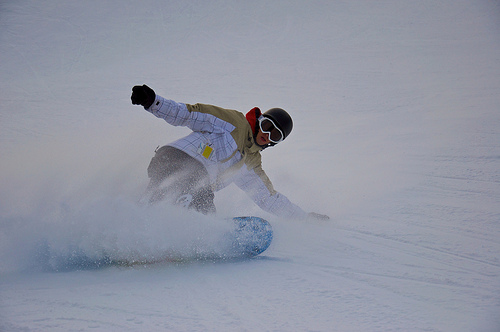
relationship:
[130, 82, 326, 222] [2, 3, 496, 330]
snowboarder coming down slope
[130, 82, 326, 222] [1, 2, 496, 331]
snowboarder stopping on snow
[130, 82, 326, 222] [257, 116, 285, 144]
snowboarder wearing goggles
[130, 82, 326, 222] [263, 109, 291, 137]
snowboarder wearing helmet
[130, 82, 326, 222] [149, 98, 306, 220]
snowboarder wearing jacket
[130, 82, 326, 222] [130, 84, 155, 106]
snowboarder wearing glove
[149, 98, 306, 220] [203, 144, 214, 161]
jacket has tag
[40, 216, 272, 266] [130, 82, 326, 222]
snowboard under snowboarder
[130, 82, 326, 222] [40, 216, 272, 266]
snowboarder on snowboard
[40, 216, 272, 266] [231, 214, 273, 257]
snowboard has tip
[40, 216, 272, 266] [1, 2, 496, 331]
snowboard behind snow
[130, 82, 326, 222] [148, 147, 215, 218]
snowboarder wearing pants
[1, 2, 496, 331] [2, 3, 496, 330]
snow on slope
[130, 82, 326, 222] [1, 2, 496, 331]
snowboarder on snow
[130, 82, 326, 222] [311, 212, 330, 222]
snowboarder has hand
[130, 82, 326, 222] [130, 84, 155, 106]
snowboarder has glove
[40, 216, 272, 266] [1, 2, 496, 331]
snowboard on snow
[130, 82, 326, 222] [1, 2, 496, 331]
snowboarder diving on snow